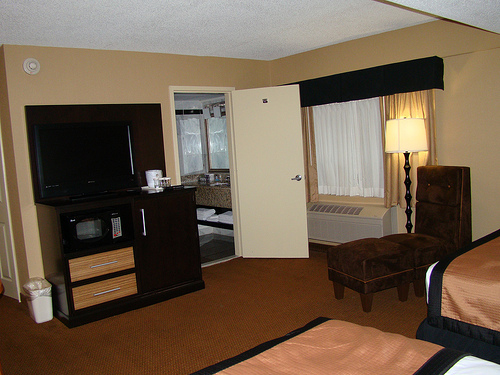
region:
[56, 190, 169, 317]
the cabinet has two drawers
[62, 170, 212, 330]
the cabinet is black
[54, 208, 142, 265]
the microwave is sitting on it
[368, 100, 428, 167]
the lamp is lit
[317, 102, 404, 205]
the white curtain is drawn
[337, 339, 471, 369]
the bed has a black & copper colored throws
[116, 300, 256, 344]
carpet is on the floor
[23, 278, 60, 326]
the trash can has a bag in it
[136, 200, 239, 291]
the cabinet appears to have a refrigerator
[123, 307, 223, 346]
the carpet is a rust colored brown.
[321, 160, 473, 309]
Brown lounge chair with buttons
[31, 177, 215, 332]
Convenience and storage console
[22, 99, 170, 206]
LCD TV atop convenience/storage cabinet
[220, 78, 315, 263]
White hotel bathroom door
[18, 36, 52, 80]
Smoke detector near ceiling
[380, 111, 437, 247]
Floor lamp near a chair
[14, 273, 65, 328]
Small wastebasket with can liner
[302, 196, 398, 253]
Wall mounted air and heating unit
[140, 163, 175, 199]
Ice bucket with tray and drinking glasses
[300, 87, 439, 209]
White sheer curtains between gold drape curtains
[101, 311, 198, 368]
The floor is brown.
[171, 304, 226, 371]
The floor is brown.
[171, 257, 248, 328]
The floor is brown.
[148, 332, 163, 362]
The floor is brown.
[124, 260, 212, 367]
The floor is brown.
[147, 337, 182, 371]
The floor is brown.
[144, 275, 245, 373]
The floor is brown.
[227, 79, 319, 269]
white door that leads to a living room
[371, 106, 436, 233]
floor lamp next to a chair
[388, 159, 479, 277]
chair is dark brown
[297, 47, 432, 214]
window of bedroom is cover with tan curtains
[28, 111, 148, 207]
big black Tv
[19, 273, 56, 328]
trash can is white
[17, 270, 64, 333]
garbage can has a plastic bag on it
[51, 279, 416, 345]
floor of bedroom is brown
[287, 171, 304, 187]
handle of door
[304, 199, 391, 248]
air conditioning in front of window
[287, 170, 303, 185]
silver door handle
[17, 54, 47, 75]
smoke detector on the wall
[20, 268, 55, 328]
white garbage can with a bag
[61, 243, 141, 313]
wooden drawers of the entertainment center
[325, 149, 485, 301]
lounge chair with a back rest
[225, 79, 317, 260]
white door to the bathroom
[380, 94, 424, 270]
lamp with the light on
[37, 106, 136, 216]
television set on a stand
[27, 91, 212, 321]
dark wood entertainment center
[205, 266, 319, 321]
dark brown carpet